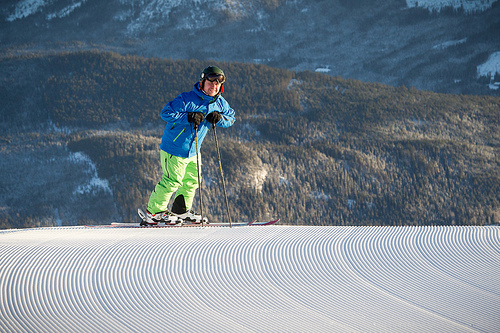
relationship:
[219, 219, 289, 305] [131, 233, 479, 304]
line in snow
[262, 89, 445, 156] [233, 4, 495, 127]
tree on hill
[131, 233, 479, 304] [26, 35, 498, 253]
snow on mountain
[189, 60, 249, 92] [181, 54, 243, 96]
helmet on head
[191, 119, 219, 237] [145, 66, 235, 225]
pole by man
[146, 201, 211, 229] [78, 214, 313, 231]
boots on skis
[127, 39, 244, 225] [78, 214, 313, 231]
man on skis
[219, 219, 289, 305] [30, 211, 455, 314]
line on ground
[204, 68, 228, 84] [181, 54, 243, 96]
goggles on head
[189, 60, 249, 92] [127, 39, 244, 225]
helmet on man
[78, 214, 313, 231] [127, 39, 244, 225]
skis on man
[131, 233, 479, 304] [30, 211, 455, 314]
snow on ground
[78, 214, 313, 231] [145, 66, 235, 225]
skis on man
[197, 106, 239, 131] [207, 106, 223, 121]
glove on hand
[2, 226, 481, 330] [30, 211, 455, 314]
ski marks on ground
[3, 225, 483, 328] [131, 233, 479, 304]
ruts in snow